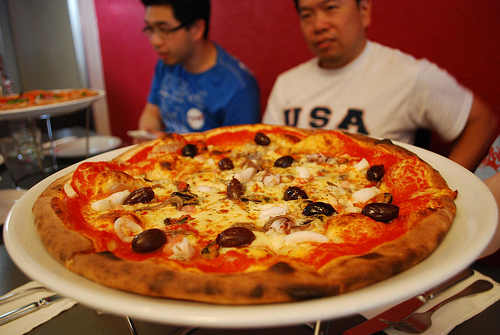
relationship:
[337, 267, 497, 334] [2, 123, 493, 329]
silverware under tray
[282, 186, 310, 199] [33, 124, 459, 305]
olve on pizza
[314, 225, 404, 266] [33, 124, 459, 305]
tomato sauce on pizza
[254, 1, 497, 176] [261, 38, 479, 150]
man wearing a shirt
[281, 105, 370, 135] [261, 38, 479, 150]
writing on shirt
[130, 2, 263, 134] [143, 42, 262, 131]
man wearing a shirt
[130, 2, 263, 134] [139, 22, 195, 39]
man wearing glasses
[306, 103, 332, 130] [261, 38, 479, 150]
s on shirt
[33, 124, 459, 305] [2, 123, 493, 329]
pizza on a tray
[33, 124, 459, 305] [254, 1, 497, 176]
pizza in front of man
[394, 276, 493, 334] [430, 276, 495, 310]
fork has a handle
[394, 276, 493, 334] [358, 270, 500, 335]
fork on napkin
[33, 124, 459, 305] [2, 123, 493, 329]
pizza on tray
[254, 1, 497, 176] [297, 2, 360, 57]
man has a face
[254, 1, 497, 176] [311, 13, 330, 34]
man has a nose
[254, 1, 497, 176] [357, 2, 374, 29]
man has an ear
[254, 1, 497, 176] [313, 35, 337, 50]
man has a mouth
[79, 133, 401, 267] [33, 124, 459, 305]
cheese on top of pizza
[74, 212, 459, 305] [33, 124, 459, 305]
crust on pizza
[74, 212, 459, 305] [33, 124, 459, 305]
crust on edge of pizza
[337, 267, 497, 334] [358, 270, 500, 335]
silverware on napkin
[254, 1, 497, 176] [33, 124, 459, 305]
man behind pizza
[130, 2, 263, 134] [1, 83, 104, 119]
man behind pizza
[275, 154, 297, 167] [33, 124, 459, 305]
olive on top of pizza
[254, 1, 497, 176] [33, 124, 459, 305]
man sitting behind pizza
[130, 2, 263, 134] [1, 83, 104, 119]
man sitting behind pizza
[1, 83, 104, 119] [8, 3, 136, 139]
pizza in background